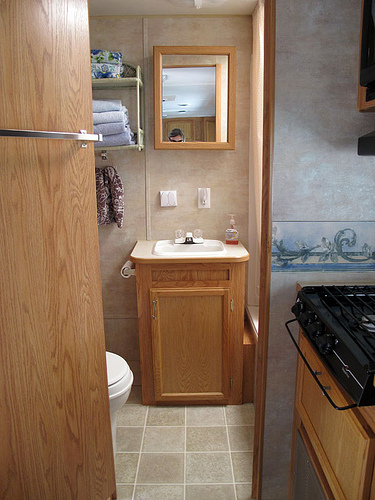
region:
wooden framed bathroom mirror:
[145, 34, 250, 163]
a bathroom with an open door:
[0, 1, 272, 496]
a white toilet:
[98, 346, 133, 454]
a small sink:
[133, 226, 245, 266]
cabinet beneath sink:
[135, 240, 248, 402]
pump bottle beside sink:
[184, 206, 245, 252]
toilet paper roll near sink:
[118, 233, 199, 291]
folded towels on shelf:
[89, 75, 148, 153]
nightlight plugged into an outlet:
[190, 177, 218, 216]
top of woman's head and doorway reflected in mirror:
[155, 46, 228, 146]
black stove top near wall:
[272, 195, 374, 420]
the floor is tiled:
[151, 424, 193, 475]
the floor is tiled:
[184, 434, 231, 498]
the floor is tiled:
[170, 435, 202, 483]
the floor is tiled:
[160, 451, 195, 498]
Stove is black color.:
[287, 269, 370, 383]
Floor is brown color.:
[130, 423, 221, 487]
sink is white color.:
[147, 232, 217, 256]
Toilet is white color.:
[102, 358, 134, 422]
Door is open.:
[72, 30, 261, 316]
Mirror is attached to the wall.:
[132, 32, 249, 154]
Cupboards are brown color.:
[141, 289, 241, 398]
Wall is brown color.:
[132, 26, 259, 214]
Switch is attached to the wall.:
[154, 185, 223, 212]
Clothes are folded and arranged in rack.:
[92, 54, 145, 171]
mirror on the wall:
[141, 27, 253, 157]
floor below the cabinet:
[166, 423, 220, 464]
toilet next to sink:
[102, 347, 138, 397]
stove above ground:
[320, 285, 373, 343]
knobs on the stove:
[287, 298, 334, 363]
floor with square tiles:
[132, 423, 222, 480]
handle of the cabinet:
[126, 293, 171, 338]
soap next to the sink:
[209, 204, 250, 259]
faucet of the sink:
[169, 222, 208, 249]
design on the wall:
[272, 221, 365, 273]